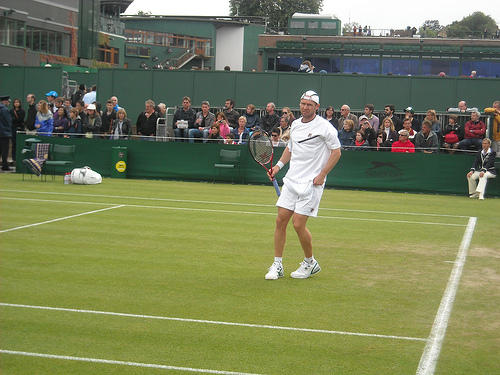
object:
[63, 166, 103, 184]
duffel bag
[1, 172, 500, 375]
court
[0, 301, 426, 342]
line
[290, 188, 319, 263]
legs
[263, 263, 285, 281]
shoe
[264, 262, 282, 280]
foot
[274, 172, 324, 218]
shorts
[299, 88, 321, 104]
hat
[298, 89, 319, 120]
head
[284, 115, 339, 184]
shirt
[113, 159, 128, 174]
dot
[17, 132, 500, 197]
fence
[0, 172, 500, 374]
ground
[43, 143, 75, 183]
chair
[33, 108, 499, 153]
stands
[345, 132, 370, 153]
woman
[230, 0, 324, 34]
trees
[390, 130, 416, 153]
man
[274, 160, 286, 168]
wristband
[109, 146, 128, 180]
trash can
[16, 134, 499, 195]
banner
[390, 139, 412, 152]
sweater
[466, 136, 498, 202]
woman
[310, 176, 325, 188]
hands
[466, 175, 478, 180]
knees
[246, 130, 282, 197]
tennis racket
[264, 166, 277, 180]
hand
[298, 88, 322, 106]
scarf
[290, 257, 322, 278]
tennis shoes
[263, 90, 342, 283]
man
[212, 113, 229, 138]
lady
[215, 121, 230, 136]
sweatshirt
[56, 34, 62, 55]
windows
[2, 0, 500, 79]
building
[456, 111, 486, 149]
spectators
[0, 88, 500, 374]
tennis match